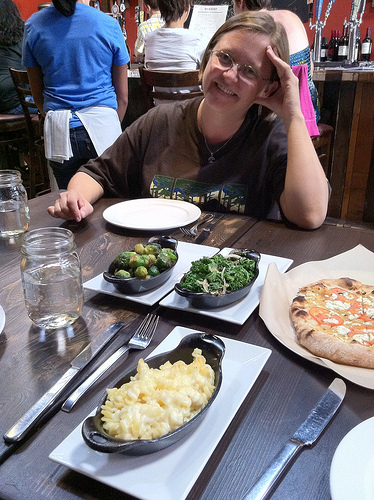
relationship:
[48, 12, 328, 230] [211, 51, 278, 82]
lady wearing glasses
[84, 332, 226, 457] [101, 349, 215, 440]
pan contains mac and cheese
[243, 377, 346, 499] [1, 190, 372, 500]
knife on top of table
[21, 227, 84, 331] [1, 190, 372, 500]
glass on top of table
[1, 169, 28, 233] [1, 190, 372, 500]
glass on top of table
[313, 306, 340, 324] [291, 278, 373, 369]
tomato on pizza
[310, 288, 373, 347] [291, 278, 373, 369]
tomato on pizza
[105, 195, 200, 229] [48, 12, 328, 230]
plate in front of lady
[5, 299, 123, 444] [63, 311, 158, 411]
knife next to fork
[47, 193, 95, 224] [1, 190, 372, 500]
hand on table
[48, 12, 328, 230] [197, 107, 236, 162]
lady wearing necklace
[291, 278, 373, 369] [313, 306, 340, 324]
pizza has tomato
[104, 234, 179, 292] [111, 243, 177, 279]
bowl contains brussel sprouts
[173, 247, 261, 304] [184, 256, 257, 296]
bowl contains vegetable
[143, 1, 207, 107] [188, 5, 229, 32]
lady looking at menu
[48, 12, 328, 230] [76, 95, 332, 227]
lady has shirt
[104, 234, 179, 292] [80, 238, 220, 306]
bowl on top of dish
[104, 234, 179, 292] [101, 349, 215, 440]
bowl contains mac and cheese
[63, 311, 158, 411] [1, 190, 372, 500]
fork on top of table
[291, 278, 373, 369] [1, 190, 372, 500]
pizza on top of table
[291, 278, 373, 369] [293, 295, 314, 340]
pizza ha burnt part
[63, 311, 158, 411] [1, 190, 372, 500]
fork on table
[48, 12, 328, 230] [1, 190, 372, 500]
lady at table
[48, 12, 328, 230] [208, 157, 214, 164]
lady wearing pendant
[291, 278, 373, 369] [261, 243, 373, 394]
pizza on paper towel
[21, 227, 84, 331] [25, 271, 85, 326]
glass contains water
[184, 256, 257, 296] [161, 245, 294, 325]
vegetable on tray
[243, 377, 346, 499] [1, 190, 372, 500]
knife on table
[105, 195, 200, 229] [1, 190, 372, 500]
plate on top of table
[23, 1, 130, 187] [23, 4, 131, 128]
waiter wearing shirt